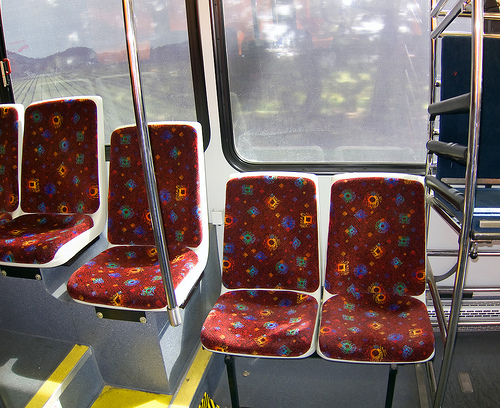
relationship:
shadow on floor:
[9, 328, 116, 401] [8, 315, 220, 406]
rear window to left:
[6, 2, 238, 171] [7, 5, 203, 408]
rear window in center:
[6, 2, 238, 171] [7, 14, 382, 372]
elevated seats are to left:
[7, 77, 113, 290] [7, 5, 203, 408]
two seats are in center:
[188, 150, 463, 382] [7, 14, 382, 372]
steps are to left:
[0, 313, 241, 407] [7, 5, 203, 408]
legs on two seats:
[220, 347, 404, 407] [188, 150, 463, 382]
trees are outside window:
[236, 5, 428, 133] [215, 5, 445, 174]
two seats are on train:
[188, 150, 463, 382] [9, 5, 497, 400]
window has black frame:
[215, 5, 445, 174] [206, 2, 255, 184]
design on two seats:
[261, 189, 297, 215] [188, 150, 463, 382]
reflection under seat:
[125, 327, 197, 384] [56, 110, 210, 327]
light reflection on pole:
[122, 16, 150, 135] [115, 4, 193, 328]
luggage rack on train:
[422, 5, 498, 398] [9, 5, 497, 400]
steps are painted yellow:
[0, 313, 241, 407] [98, 390, 174, 407]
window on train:
[215, 5, 445, 174] [9, 5, 497, 400]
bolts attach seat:
[93, 312, 148, 329] [56, 110, 210, 327]